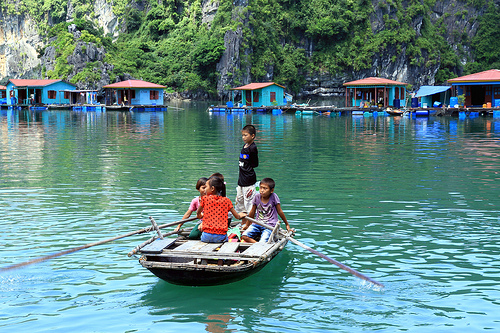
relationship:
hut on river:
[230, 80, 286, 107] [1, 97, 499, 332]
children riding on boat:
[174, 124, 291, 244] [128, 219, 297, 286]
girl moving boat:
[197, 178, 250, 245] [128, 219, 297, 286]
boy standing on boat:
[235, 124, 258, 226] [128, 219, 297, 286]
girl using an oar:
[197, 178, 250, 245] [245, 216, 385, 289]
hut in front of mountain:
[230, 80, 286, 107] [1, 0, 500, 98]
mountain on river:
[1, 0, 500, 98] [1, 97, 499, 332]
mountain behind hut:
[1, 0, 500, 98] [230, 80, 286, 107]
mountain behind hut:
[1, 0, 500, 98] [5, 77, 78, 107]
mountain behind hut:
[1, 0, 500, 98] [102, 79, 166, 109]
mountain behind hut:
[1, 0, 500, 98] [342, 77, 407, 110]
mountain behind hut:
[1, 0, 500, 98] [414, 85, 453, 115]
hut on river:
[5, 77, 78, 107] [1, 97, 499, 332]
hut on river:
[102, 79, 166, 109] [1, 97, 499, 332]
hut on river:
[342, 77, 407, 110] [1, 97, 499, 332]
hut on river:
[414, 85, 453, 115] [1, 97, 499, 332]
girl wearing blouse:
[197, 178, 250, 245] [198, 194, 234, 235]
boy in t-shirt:
[235, 124, 258, 226] [238, 141, 259, 187]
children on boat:
[174, 124, 291, 244] [128, 219, 297, 286]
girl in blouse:
[197, 178, 250, 245] [198, 194, 234, 235]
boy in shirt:
[240, 178, 291, 244] [252, 192, 280, 227]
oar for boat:
[245, 216, 385, 289] [128, 219, 297, 286]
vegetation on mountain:
[1, 1, 500, 97] [1, 0, 500, 98]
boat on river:
[128, 219, 297, 286] [1, 97, 499, 332]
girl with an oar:
[197, 178, 250, 245] [245, 216, 385, 289]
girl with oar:
[197, 178, 250, 245] [1, 216, 200, 271]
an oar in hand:
[245, 216, 385, 289] [238, 211, 248, 218]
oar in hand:
[1, 216, 200, 271] [197, 212, 203, 220]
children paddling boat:
[174, 124, 291, 244] [128, 219, 297, 286]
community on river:
[0, 69, 499, 118] [1, 97, 499, 332]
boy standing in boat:
[235, 124, 258, 226] [128, 219, 297, 286]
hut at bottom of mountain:
[230, 80, 286, 107] [1, 0, 500, 98]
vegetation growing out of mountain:
[1, 1, 500, 97] [1, 0, 500, 98]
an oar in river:
[245, 216, 385, 289] [1, 97, 499, 332]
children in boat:
[174, 124, 291, 244] [128, 219, 297, 286]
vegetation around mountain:
[1, 1, 500, 97] [1, 0, 500, 98]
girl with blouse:
[197, 178, 250, 245] [198, 194, 234, 235]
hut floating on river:
[230, 80, 286, 107] [1, 97, 499, 332]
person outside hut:
[29, 91, 35, 104] [5, 77, 78, 107]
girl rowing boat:
[197, 178, 250, 245] [128, 219, 297, 286]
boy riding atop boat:
[235, 124, 258, 226] [128, 219, 297, 286]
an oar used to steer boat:
[245, 216, 385, 289] [128, 219, 297, 286]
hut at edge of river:
[230, 80, 286, 107] [1, 97, 499, 332]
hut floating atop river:
[230, 80, 286, 107] [1, 97, 499, 332]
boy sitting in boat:
[240, 178, 291, 244] [128, 219, 297, 286]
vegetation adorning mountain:
[1, 1, 500, 97] [1, 0, 500, 98]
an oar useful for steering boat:
[245, 216, 385, 289] [128, 219, 297, 286]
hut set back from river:
[230, 80, 286, 107] [1, 97, 499, 332]